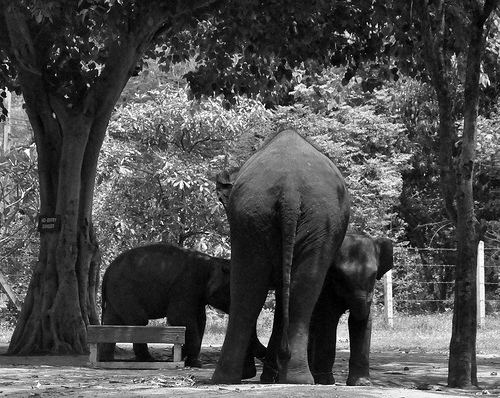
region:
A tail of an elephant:
[275, 198, 305, 330]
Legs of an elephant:
[221, 265, 322, 382]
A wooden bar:
[87, 319, 183, 359]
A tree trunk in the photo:
[447, 249, 495, 350]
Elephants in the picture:
[141, 195, 406, 372]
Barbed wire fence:
[378, 235, 468, 320]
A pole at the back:
[385, 242, 405, 322]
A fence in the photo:
[412, 242, 436, 312]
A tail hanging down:
[280, 193, 298, 335]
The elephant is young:
[99, 243, 234, 370]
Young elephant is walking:
[303, 233, 391, 385]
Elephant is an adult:
[210, 127, 347, 382]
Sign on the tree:
[37, 212, 60, 232]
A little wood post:
[85, 326, 185, 368]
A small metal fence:
[370, 241, 496, 327]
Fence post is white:
[477, 241, 485, 327]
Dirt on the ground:
[0, 356, 498, 393]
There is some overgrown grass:
[371, 313, 498, 348]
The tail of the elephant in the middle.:
[270, 177, 296, 327]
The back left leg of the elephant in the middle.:
[221, 238, 257, 383]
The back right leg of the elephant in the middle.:
[263, 246, 316, 387]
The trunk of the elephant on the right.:
[335, 282, 370, 381]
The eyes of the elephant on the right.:
[335, 265, 382, 285]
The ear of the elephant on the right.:
[379, 237, 394, 279]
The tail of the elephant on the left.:
[99, 270, 108, 322]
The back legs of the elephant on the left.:
[100, 296, 151, 369]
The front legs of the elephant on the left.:
[163, 299, 210, 359]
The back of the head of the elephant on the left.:
[207, 252, 238, 320]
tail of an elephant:
[274, 177, 299, 367]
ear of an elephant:
[376, 236, 394, 280]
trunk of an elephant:
[346, 282, 370, 394]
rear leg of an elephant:
[215, 207, 255, 387]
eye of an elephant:
[371, 266, 378, 281]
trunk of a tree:
[426, 69, 487, 394]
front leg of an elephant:
[309, 302, 344, 393]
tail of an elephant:
[97, 273, 105, 326]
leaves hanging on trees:
[1, 3, 498, 114]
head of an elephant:
[338, 236, 384, 310]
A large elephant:
[208, 115, 336, 396]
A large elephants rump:
[209, 130, 330, 384]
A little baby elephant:
[97, 242, 227, 349]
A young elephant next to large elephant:
[311, 213, 392, 379]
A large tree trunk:
[16, 93, 90, 344]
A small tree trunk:
[426, 91, 498, 386]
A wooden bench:
[78, 318, 199, 379]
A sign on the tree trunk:
[25, 203, 66, 238]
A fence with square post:
[366, 218, 491, 340]